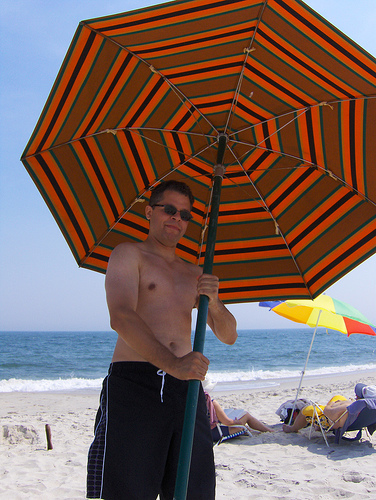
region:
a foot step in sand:
[338, 468, 365, 485]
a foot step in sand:
[267, 474, 296, 492]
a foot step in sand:
[241, 460, 269, 486]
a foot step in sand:
[297, 459, 317, 478]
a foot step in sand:
[284, 440, 307, 457]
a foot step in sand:
[19, 455, 34, 468]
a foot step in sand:
[19, 479, 49, 495]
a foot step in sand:
[51, 461, 74, 481]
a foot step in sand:
[67, 444, 77, 453]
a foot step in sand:
[49, 406, 68, 424]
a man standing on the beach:
[93, 179, 225, 495]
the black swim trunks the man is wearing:
[77, 354, 209, 498]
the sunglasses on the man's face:
[150, 200, 192, 225]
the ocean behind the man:
[5, 326, 367, 389]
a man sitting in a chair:
[288, 389, 353, 432]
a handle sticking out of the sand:
[32, 419, 55, 450]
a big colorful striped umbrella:
[21, 2, 375, 310]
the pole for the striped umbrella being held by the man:
[167, 140, 225, 498]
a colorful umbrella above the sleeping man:
[261, 291, 374, 345]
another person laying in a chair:
[207, 394, 268, 445]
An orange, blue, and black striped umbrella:
[63, 7, 356, 170]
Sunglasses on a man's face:
[146, 194, 198, 226]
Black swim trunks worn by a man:
[88, 344, 212, 469]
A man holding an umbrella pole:
[107, 180, 218, 431]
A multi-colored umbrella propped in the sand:
[266, 285, 367, 331]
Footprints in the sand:
[230, 457, 304, 487]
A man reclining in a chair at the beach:
[287, 380, 368, 432]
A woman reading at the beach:
[212, 379, 259, 441]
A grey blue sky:
[16, 233, 69, 311]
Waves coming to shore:
[9, 367, 92, 397]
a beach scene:
[12, 3, 356, 491]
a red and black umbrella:
[12, 2, 375, 383]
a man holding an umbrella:
[17, 0, 374, 490]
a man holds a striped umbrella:
[13, 8, 375, 479]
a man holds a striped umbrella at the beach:
[13, 4, 374, 497]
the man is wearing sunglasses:
[88, 172, 259, 495]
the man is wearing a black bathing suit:
[91, 174, 231, 496]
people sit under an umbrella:
[193, 285, 374, 452]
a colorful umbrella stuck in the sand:
[266, 287, 375, 439]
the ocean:
[8, 324, 372, 385]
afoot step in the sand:
[24, 473, 44, 493]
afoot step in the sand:
[15, 425, 34, 444]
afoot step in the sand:
[7, 443, 23, 459]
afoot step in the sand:
[19, 482, 45, 495]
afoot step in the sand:
[244, 468, 270, 479]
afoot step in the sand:
[215, 461, 230, 478]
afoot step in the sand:
[341, 468, 358, 485]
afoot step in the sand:
[298, 463, 315, 469]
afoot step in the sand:
[330, 453, 338, 463]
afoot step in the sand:
[320, 486, 350, 498]